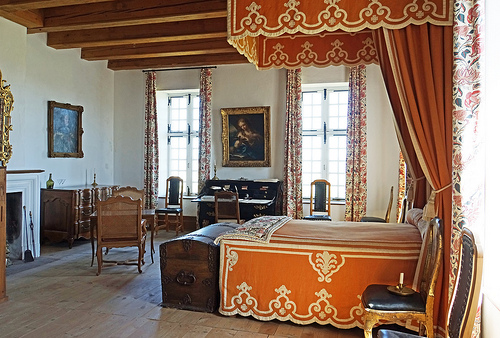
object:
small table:
[89, 209, 157, 262]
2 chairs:
[89, 181, 157, 277]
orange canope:
[225, 0, 449, 227]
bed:
[219, 209, 449, 327]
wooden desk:
[192, 193, 274, 222]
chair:
[213, 191, 245, 226]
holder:
[388, 282, 414, 297]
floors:
[26, 252, 102, 294]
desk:
[191, 179, 282, 229]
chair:
[360, 228, 451, 338]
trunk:
[212, 210, 295, 312]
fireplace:
[0, 167, 47, 263]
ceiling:
[27, 2, 227, 66]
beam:
[44, 6, 245, 33]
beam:
[80, 41, 252, 63]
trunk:
[159, 216, 240, 313]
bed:
[220, 0, 452, 327]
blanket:
[210, 216, 291, 247]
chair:
[92, 195, 146, 276]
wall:
[0, 50, 119, 245]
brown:
[160, 242, 215, 313]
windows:
[154, 89, 200, 198]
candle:
[398, 271, 405, 286]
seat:
[358, 281, 425, 313]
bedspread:
[214, 207, 439, 327]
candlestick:
[211, 165, 220, 181]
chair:
[377, 228, 484, 338]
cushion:
[361, 280, 423, 310]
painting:
[226, 113, 265, 161]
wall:
[110, 67, 283, 218]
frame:
[218, 105, 272, 168]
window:
[291, 81, 354, 218]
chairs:
[103, 186, 156, 264]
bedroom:
[5, 5, 482, 333]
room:
[2, 5, 492, 333]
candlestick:
[386, 282, 416, 296]